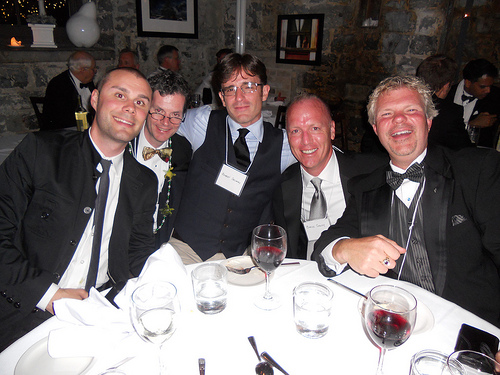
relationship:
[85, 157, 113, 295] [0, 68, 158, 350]
black tie on man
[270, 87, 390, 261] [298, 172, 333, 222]
man wears tie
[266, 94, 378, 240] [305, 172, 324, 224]
man wears tie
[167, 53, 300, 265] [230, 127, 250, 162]
man wears tie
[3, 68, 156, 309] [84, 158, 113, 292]
man wears black tie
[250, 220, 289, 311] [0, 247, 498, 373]
wine on table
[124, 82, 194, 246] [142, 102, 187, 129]
guy wearing glasses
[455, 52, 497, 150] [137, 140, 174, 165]
guy wearing gold bowtie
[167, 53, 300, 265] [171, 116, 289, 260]
man wearing vest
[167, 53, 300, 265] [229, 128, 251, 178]
man wearing tie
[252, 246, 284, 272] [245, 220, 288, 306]
wine in glass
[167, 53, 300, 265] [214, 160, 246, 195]
man wearing tag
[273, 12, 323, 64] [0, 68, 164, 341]
photo behind man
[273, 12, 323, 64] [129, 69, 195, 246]
photo behind guy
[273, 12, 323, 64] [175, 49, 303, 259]
photo behind man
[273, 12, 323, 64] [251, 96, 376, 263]
photo behind man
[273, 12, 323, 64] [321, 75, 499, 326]
photo behind man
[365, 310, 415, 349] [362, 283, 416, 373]
wine in glass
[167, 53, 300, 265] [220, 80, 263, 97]
man has glasses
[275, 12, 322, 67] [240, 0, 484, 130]
photo hanging on wall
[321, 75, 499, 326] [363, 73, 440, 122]
man has short hair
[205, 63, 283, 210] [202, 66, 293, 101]
man wearing glasses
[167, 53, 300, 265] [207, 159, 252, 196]
man wearing badge